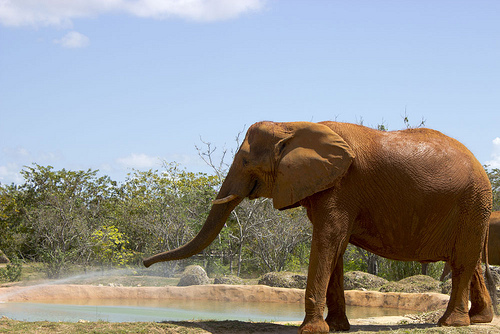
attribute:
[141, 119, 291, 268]
head — top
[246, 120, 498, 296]
elephant — orange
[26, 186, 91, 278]
bush — small, safari bush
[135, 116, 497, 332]
elephant — brown, smirking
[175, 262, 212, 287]
rock — large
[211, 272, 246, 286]
rock — large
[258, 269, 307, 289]
rock — large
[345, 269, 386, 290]
rock — large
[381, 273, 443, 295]
rock — large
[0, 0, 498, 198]
sky — Blue, white, clear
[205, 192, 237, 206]
tusk — white, ivory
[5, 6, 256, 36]
clouds — White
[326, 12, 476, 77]
sky — Blue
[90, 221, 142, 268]
bush — small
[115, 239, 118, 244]
foliage — lime, green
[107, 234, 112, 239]
foliage — green, lime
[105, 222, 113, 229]
foliage — green, lime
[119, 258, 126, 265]
foliage — green, lime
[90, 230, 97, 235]
foliage — green, lime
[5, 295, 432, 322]
water — clear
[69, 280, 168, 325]
creek — clear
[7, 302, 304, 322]
water — small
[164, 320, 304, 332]
shadow — dark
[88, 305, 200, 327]
water — blue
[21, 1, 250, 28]
clouds — white, whispy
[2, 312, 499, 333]
grass — dry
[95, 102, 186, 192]
clouds — white, wispy